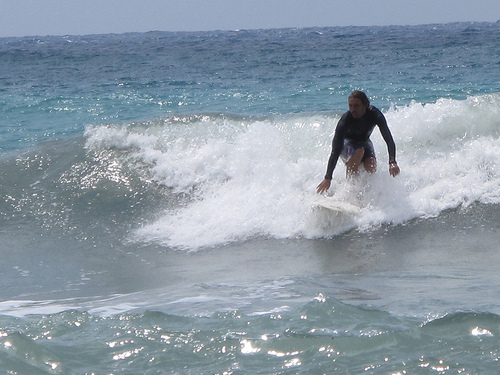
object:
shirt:
[322, 106, 400, 180]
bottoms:
[332, 137, 381, 168]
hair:
[346, 90, 372, 111]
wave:
[80, 91, 499, 242]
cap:
[85, 89, 498, 256]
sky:
[1, 1, 498, 21]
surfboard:
[296, 191, 375, 219]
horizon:
[0, 11, 498, 40]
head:
[346, 88, 371, 125]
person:
[317, 88, 403, 201]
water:
[0, 40, 316, 374]